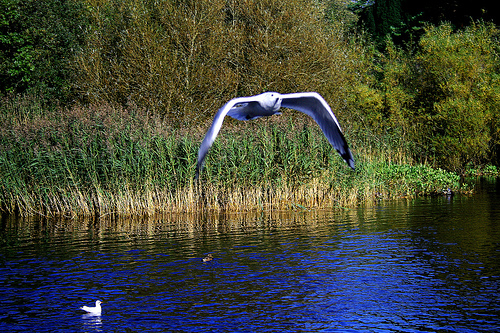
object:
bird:
[194, 87, 358, 173]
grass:
[0, 90, 500, 217]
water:
[1, 185, 499, 332]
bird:
[78, 298, 106, 316]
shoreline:
[0, 174, 500, 221]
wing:
[194, 94, 249, 168]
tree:
[51, 0, 358, 122]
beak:
[95, 300, 104, 305]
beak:
[271, 96, 283, 107]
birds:
[198, 251, 220, 264]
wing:
[282, 89, 358, 172]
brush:
[0, 90, 460, 218]